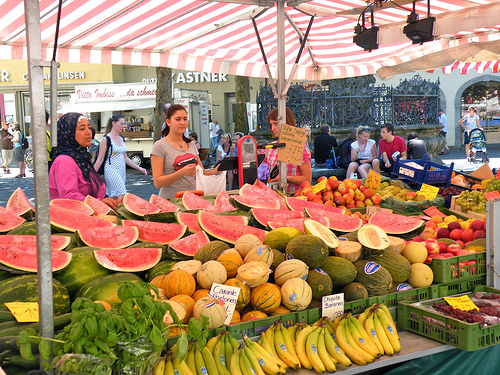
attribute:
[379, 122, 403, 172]
man — dating, white, caucasian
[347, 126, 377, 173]
woman — dating, caucasian, white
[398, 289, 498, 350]
crate — sturdy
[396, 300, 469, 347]
edge — straight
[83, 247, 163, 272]
watermelon — red, delicious, inviting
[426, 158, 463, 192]
ground — paved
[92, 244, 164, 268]
green watermelon — ripe, hearty, fresh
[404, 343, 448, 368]
table — green, painted, wooden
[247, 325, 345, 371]
yellow bananas — fresh, whole, ripening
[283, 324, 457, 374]
table — wooden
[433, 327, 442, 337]
edge — perforated, straight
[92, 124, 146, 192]
dress — sleeveless, knee-length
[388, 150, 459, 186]
train — small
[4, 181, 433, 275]
watermelon — red, quartered, juicy, succulent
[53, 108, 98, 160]
woman's head — Indian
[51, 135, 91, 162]
neck — long, graceful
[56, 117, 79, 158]
wrap — black, customary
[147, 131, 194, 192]
shirt — fitted, cartoon, screen-printed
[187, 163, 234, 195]
bag — open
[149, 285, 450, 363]
bananas — are yellow, are delicious, are ripening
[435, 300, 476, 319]
merchandise — fragile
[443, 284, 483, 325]
merchandise — fragile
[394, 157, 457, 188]
crate — black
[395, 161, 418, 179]
crate side — strong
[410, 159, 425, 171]
fruit — fresh, market stand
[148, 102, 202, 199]
lady — young, pretty, consumer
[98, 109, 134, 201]
woman — white, sweating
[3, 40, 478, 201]
town — bustling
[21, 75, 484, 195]
town — urbanized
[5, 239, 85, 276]
watermelon — ripe, sweet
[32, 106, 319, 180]
consumers — are interested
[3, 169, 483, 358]
fruit stand — abundant, fresh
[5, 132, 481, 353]
fruit stand — centralized, popular, fresh